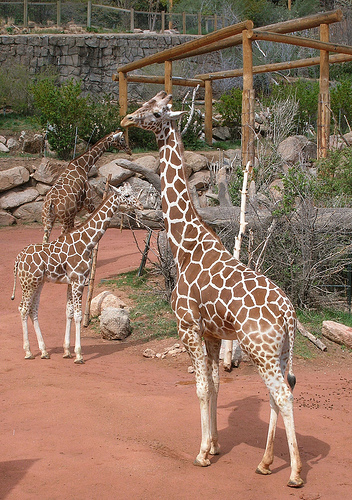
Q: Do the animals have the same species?
A: Yes, all the animals are giraffes.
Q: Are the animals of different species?
A: No, all the animals are giraffes.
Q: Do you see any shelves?
A: No, there are no shelves.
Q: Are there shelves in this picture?
A: No, there are no shelves.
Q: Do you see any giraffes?
A: Yes, there is a giraffe.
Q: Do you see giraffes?
A: Yes, there is a giraffe.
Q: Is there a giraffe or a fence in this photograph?
A: Yes, there is a giraffe.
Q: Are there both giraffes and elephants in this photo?
A: No, there is a giraffe but no elephants.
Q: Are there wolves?
A: No, there are no wolves.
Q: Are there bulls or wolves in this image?
A: No, there are no wolves or bulls.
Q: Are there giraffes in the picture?
A: Yes, there is a giraffe.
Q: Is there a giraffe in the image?
A: Yes, there is a giraffe.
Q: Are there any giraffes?
A: Yes, there is a giraffe.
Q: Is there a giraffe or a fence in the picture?
A: Yes, there is a giraffe.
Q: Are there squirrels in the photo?
A: No, there are no squirrels.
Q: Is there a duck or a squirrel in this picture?
A: No, there are no squirrels or ducks.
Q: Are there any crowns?
A: No, there are no crowns.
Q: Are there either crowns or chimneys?
A: No, there are no crowns or chimneys.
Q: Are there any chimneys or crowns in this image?
A: No, there are no crowns or chimneys.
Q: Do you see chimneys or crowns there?
A: No, there are no crowns or chimneys.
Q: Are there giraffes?
A: Yes, there is a giraffe.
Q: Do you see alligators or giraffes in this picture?
A: Yes, there is a giraffe.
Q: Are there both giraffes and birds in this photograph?
A: No, there is a giraffe but no birds.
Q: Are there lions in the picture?
A: No, there are no lions.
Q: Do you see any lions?
A: No, there are no lions.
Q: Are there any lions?
A: No, there are no lions.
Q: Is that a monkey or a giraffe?
A: That is a giraffe.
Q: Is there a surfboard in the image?
A: No, there are no surfboards.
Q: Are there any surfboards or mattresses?
A: No, there are no surfboards or mattresses.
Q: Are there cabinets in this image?
A: No, there are no cabinets.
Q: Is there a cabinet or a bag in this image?
A: No, there are no cabinets or bags.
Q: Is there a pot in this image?
A: No, there are no pots.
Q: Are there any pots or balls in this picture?
A: No, there are no pots or balls.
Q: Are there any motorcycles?
A: No, there are no motorcycles.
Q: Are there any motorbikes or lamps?
A: No, there are no motorbikes or lamps.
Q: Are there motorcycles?
A: No, there are no motorcycles.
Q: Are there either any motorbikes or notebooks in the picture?
A: No, there are no motorbikes or notebooks.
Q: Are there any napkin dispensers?
A: No, there are no napkin dispensers.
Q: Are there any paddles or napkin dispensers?
A: No, there are no napkin dispensers or paddles.